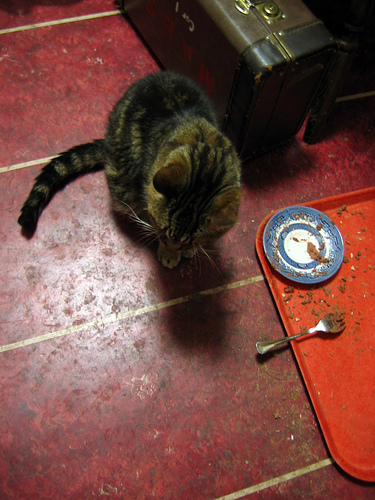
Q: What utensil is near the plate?
A: A fork.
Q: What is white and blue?
A: A saucer.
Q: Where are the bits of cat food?
A: On the saucer.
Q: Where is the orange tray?
A: On the floor.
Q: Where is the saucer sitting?
A: On the tray.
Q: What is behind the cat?
A: A suitcase.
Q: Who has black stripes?
A: A cat.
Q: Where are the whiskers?
A: On the cat face.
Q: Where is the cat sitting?
A: On the floor.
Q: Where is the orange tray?
A: On the floor.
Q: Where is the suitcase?
A: On the floor.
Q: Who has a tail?
A: The cat.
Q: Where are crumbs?
A: On plate and tray.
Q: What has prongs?
A: The fork.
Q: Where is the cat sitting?
A: On the floor.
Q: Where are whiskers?
A: On cat's face.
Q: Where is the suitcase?
A: On the floor.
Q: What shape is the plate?
A: Round.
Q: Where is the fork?
A: On tray.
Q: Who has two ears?
A: A cat.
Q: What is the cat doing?
A: Sitting on a floor.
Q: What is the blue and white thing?
A: A blue and white saucer.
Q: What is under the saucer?
A: An orange tray.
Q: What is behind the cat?
A: Suitcase.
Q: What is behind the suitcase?
A: A table leg.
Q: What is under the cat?
A: A red tile floor.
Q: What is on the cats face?
A: White whiskers.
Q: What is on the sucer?
A: Cat food.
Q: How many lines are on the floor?
A: 4.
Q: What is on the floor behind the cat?
A: Suitcase.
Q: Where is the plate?
A: On the tray.